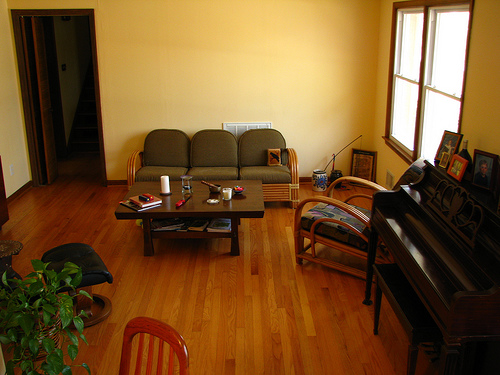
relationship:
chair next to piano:
[283, 156, 425, 289] [358, 151, 496, 369]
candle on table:
[159, 173, 170, 193] [114, 178, 264, 216]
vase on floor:
[309, 169, 329, 192] [2, 175, 386, 373]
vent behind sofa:
[221, 119, 274, 139] [128, 127, 298, 182]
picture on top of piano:
[470, 148, 499, 190] [361, 129, 499, 372]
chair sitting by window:
[283, 156, 425, 289] [380, 2, 478, 186]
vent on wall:
[221, 119, 274, 139] [3, 3, 378, 183]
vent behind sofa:
[221, 119, 274, 139] [122, 123, 302, 206]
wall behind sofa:
[3, 3, 378, 183] [122, 123, 302, 206]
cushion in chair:
[299, 190, 371, 250] [283, 156, 425, 289]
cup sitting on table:
[218, 185, 235, 198] [111, 174, 266, 257]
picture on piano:
[469, 143, 499, 190] [358, 151, 496, 369]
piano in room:
[358, 151, 496, 369] [1, 1, 499, 368]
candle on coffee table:
[159, 175, 170, 194] [113, 172, 268, 258]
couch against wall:
[119, 124, 302, 214] [3, 3, 378, 183]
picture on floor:
[347, 147, 379, 190] [4, 174, 443, 372]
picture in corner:
[347, 147, 379, 190] [311, 1, 389, 196]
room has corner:
[1, 1, 499, 368] [311, 1, 389, 196]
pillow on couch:
[264, 145, 284, 168] [119, 124, 302, 214]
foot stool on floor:
[38, 241, 114, 331] [4, 174, 443, 372]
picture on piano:
[443, 151, 469, 185] [358, 151, 496, 369]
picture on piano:
[434, 127, 463, 168] [358, 151, 496, 369]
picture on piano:
[470, 148, 499, 190] [358, 151, 496, 369]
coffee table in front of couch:
[108, 179, 268, 257] [119, 124, 302, 214]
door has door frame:
[9, 3, 112, 190] [5, 1, 113, 184]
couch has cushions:
[119, 124, 302, 214] [138, 125, 294, 187]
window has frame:
[381, 10, 471, 178] [385, 3, 474, 173]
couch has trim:
[119, 124, 302, 214] [120, 149, 301, 206]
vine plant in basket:
[0, 257, 91, 373] [11, 308, 63, 370]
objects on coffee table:
[119, 166, 243, 216] [104, 167, 272, 253]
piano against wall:
[358, 151, 496, 369] [375, 2, 495, 192]